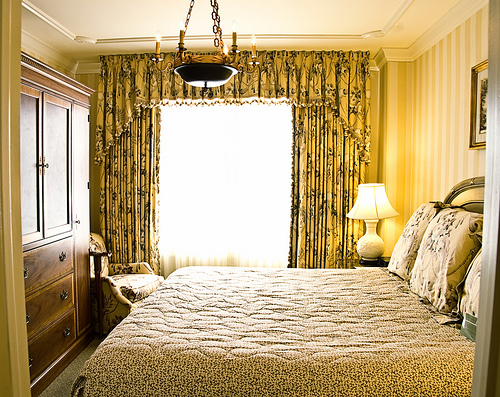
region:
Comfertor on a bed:
[161, 256, 397, 358]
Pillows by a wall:
[376, 191, 499, 307]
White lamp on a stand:
[342, 175, 392, 267]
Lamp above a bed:
[156, 3, 259, 93]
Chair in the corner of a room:
[78, 231, 165, 327]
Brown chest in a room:
[15, 48, 133, 382]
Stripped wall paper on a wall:
[359, 40, 479, 201]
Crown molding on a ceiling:
[48, 12, 396, 75]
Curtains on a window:
[86, 53, 387, 275]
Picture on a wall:
[457, 52, 499, 155]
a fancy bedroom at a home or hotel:
[31, 10, 471, 321]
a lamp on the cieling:
[65, 7, 365, 101]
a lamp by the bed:
[338, 159, 418, 282]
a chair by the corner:
[78, 210, 173, 330]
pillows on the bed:
[365, 175, 480, 328]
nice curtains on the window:
[93, 27, 391, 260]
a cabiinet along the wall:
[18, 37, 125, 314]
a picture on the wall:
[434, 46, 491, 150]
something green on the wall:
[423, 280, 482, 350]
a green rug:
[28, 310, 116, 395]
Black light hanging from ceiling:
[134, 3, 273, 118]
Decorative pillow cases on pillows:
[365, 184, 480, 309]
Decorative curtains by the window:
[93, 76, 378, 273]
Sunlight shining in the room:
[118, 89, 355, 344]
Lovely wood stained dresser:
[23, 38, 123, 394]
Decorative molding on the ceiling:
[42, 16, 426, 66]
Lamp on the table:
[329, 155, 416, 281]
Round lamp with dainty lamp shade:
[331, 169, 404, 262]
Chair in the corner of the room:
[90, 222, 175, 344]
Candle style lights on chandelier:
[136, 25, 276, 69]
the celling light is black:
[170, 0, 242, 91]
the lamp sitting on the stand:
[345, 181, 393, 263]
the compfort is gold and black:
[70, 261, 474, 392]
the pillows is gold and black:
[379, 197, 478, 329]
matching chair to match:
[87, 230, 166, 336]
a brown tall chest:
[15, 73, 93, 392]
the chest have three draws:
[23, 228, 83, 380]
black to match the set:
[87, 71, 369, 273]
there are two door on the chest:
[15, 80, 73, 248]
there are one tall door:
[69, 103, 92, 338]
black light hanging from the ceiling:
[172, 0, 241, 92]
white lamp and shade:
[341, 179, 400, 265]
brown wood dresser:
[17, 45, 99, 392]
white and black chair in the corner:
[85, 230, 162, 341]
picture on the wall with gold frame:
[466, 56, 491, 151]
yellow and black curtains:
[92, 51, 370, 273]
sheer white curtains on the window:
[155, 102, 292, 269]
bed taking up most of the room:
[75, 174, 484, 396]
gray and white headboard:
[439, 172, 490, 211]